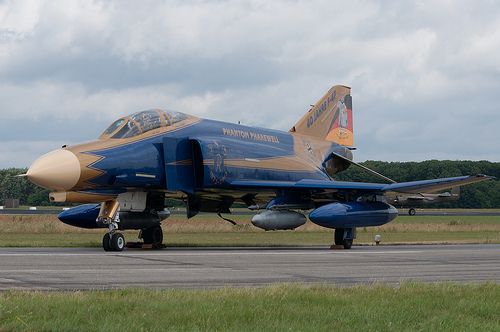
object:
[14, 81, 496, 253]
fighter jet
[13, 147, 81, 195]
nose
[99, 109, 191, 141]
cockpit window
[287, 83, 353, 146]
tail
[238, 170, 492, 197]
left wing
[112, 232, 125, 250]
front wheel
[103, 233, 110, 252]
front wheel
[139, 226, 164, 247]
right bach wheel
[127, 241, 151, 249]
chocks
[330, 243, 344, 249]
chocks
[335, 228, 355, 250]
left back wheel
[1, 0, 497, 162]
clouds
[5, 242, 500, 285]
runway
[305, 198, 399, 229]
engine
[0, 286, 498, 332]
grass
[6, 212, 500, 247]
grass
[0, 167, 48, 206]
trees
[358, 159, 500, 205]
trees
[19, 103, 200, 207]
front part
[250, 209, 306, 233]
rocket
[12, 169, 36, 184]
sharpe edge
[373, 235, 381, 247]
object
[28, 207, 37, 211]
post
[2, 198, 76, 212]
grass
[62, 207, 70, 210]
post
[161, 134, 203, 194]
open door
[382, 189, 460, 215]
military plane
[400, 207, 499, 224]
tarmac